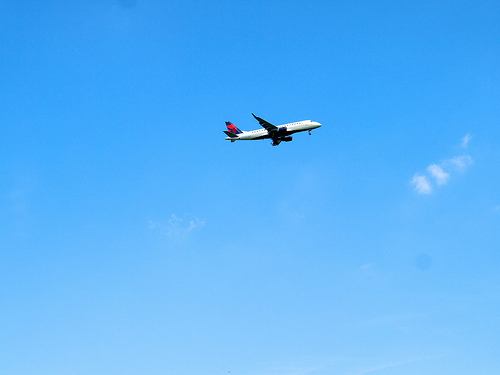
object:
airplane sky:
[0, 0, 500, 374]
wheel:
[273, 135, 294, 148]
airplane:
[223, 112, 320, 146]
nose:
[301, 119, 326, 130]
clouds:
[411, 138, 500, 200]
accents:
[219, 121, 244, 141]